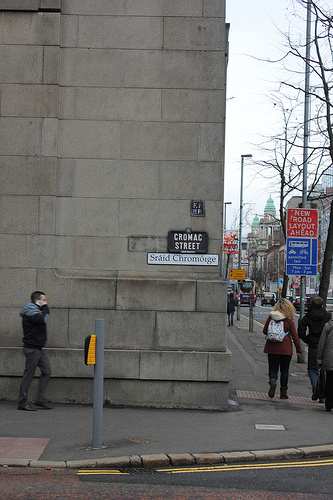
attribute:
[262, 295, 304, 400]
woman — curly haired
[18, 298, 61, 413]
clothing — black and gray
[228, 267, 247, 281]
sign — yellow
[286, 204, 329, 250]
sign — red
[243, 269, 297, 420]
woman — blonde haired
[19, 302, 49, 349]
hoodie — black, gray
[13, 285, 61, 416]
man — talking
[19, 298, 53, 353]
jacket — black, gray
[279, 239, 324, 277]
sign — blue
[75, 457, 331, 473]
lines — yellow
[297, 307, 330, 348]
coat — black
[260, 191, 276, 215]
blue building — big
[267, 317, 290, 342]
backpack — small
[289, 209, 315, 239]
letters — white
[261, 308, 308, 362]
coat — brown